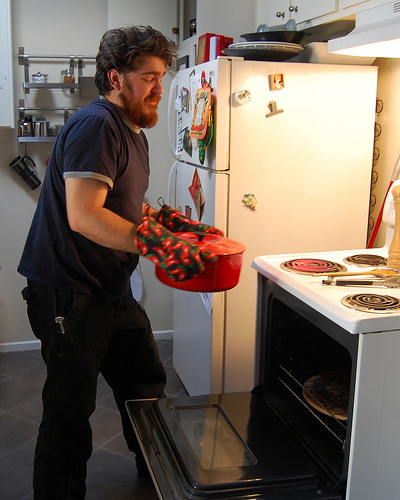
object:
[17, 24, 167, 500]
man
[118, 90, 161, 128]
beard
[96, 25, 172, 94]
hair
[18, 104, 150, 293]
shirt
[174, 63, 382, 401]
refrigerator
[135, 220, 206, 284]
gloves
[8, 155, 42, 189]
bottle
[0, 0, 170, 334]
wall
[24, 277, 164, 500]
pants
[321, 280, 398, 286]
utensils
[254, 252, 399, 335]
stove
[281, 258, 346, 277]
burner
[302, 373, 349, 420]
pizza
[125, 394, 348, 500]
oven door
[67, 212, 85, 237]
elbow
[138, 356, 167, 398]
knee area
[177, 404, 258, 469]
window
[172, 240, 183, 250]
red pepper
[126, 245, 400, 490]
oven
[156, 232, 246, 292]
pot